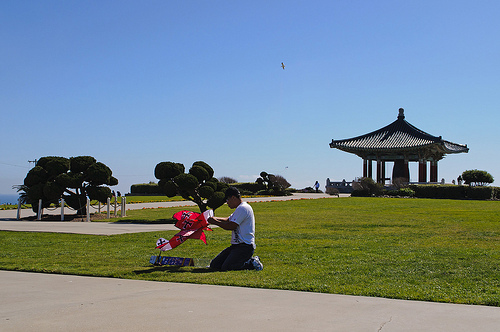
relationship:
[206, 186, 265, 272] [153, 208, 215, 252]
man holding kite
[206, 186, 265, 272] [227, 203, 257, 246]
man wearing t-shirt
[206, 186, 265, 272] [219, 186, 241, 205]
man wearing baseball cap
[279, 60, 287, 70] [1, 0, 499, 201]
bird in sky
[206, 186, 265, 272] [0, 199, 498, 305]
man on grass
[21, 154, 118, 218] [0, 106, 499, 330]
bush in park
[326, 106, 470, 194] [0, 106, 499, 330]
pagoda in park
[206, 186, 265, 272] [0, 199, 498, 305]
man kneeling on grass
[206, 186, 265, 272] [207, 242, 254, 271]
man wearing jeans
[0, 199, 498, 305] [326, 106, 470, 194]
grass in front of pagoda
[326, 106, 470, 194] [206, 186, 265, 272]
pagoda behind man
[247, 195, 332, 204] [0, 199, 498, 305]
plants next to grass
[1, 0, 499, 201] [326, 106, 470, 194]
sky behind pagoda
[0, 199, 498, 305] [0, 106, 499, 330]
grass in park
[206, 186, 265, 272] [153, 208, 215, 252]
man looking at kite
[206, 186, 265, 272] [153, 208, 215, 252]
man fixing kite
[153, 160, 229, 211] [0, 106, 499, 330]
tree in park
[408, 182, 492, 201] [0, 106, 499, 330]
bush in park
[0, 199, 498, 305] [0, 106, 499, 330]
grass inside park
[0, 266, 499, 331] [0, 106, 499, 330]
sidewalk in park